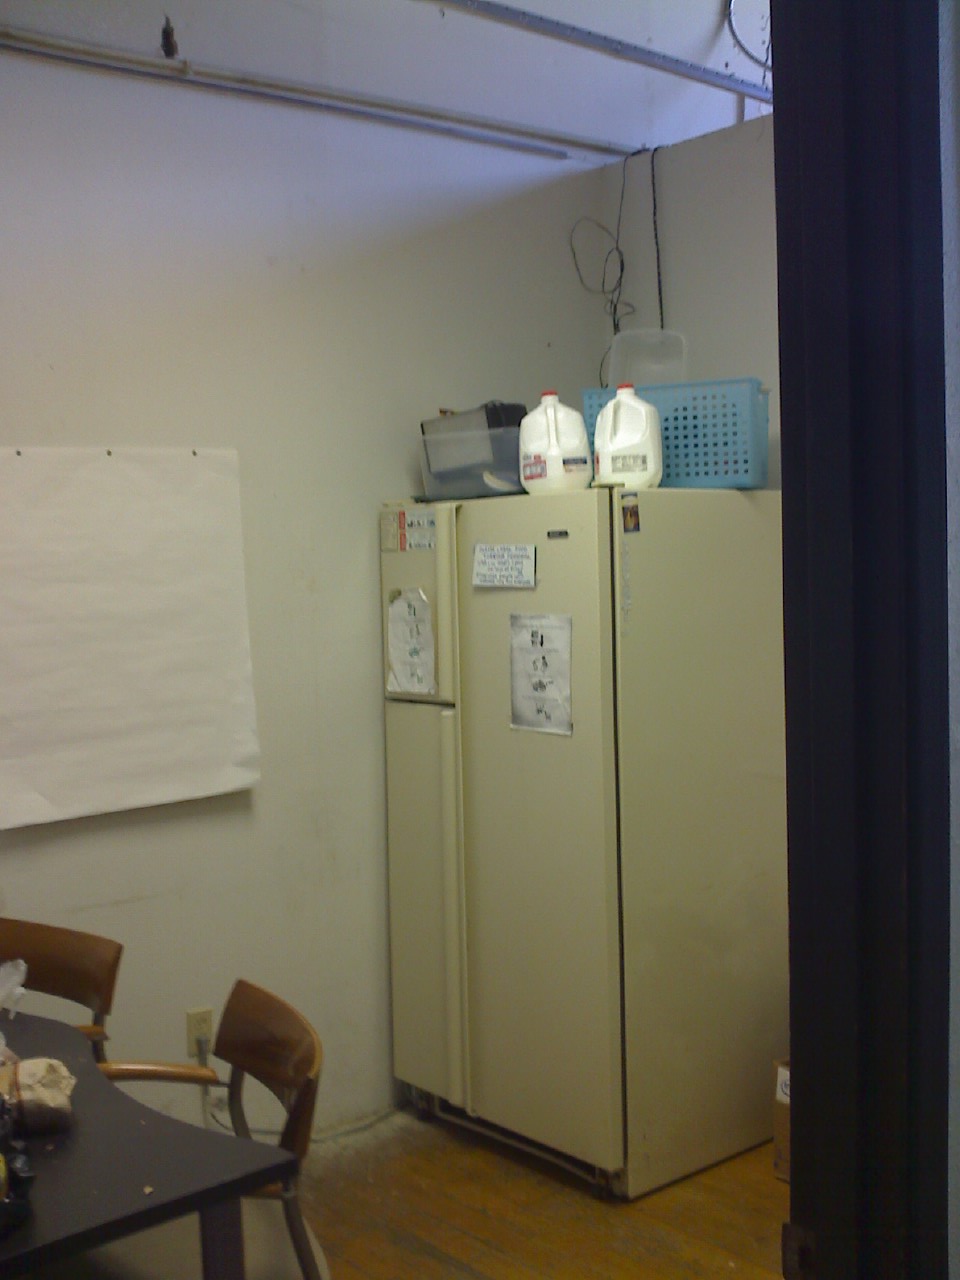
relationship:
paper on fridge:
[473, 534, 562, 605] [343, 444, 754, 1208]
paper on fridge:
[499, 603, 568, 729] [246, 327, 797, 1267]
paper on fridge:
[615, 485, 628, 524] [116, 275, 843, 1259]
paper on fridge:
[385, 509, 441, 547] [277, 390, 812, 1213]